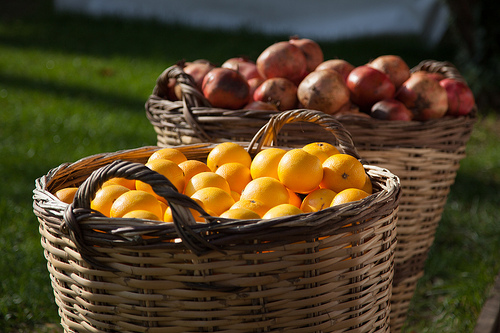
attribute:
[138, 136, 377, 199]
orange — bright, yellow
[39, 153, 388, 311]
basket — brown, wicker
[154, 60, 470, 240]
basket — wicker, brown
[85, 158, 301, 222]
food — yellow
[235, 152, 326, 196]
fruit — round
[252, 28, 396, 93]
food — purple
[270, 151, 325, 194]
lemon — yellow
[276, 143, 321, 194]
lemon — yellow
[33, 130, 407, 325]
lemon — yellow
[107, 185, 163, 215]
lemon — yellow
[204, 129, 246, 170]
lemon — yellow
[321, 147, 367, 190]
lemon — yellow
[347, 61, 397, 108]
potato — red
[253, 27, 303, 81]
potato — red